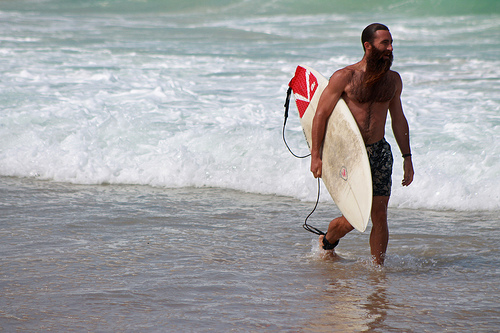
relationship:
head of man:
[362, 23, 394, 67] [311, 23, 416, 267]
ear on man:
[364, 40, 372, 53] [311, 23, 416, 267]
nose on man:
[387, 41, 393, 51] [311, 23, 416, 267]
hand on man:
[310, 157, 323, 180] [311, 23, 416, 267]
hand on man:
[401, 155, 415, 186] [311, 23, 416, 267]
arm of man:
[310, 68, 345, 179] [311, 23, 416, 267]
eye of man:
[382, 39, 389, 45] [311, 23, 416, 267]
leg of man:
[369, 141, 393, 264] [311, 23, 416, 267]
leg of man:
[326, 216, 354, 244] [311, 23, 416, 267]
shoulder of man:
[390, 70, 403, 96] [311, 23, 416, 267]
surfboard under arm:
[290, 62, 373, 234] [310, 68, 345, 179]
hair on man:
[361, 22, 389, 52] [311, 23, 416, 267]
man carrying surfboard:
[311, 23, 416, 267] [290, 62, 373, 234]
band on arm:
[401, 152, 411, 157] [390, 70, 414, 186]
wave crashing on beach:
[2, 85, 500, 211] [1, 176, 499, 333]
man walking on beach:
[311, 23, 416, 267] [1, 176, 499, 333]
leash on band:
[301, 178, 324, 237] [321, 232, 339, 251]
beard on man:
[365, 45, 395, 89] [311, 23, 416, 267]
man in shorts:
[311, 23, 416, 267] [366, 137, 394, 198]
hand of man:
[310, 157, 323, 180] [311, 23, 416, 267]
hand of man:
[401, 155, 415, 186] [311, 23, 416, 267]